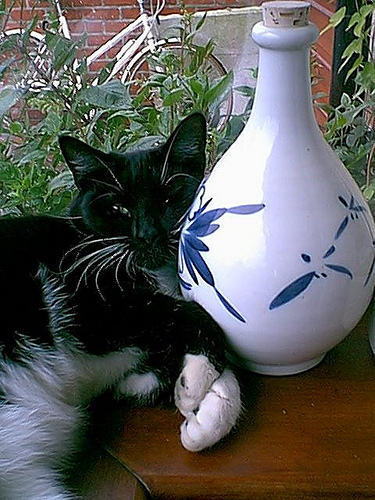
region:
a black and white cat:
[4, 117, 265, 498]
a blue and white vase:
[149, 33, 373, 388]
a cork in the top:
[261, 1, 322, 37]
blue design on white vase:
[164, 178, 371, 333]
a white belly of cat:
[12, 346, 116, 499]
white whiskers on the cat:
[54, 224, 170, 298]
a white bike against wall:
[18, 3, 244, 162]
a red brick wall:
[6, 3, 338, 161]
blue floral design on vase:
[176, 173, 373, 312]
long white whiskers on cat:
[49, 233, 145, 291]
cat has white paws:
[170, 354, 243, 453]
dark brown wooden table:
[258, 382, 355, 480]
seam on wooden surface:
[89, 435, 148, 497]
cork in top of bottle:
[259, 0, 314, 28]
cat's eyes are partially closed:
[103, 194, 186, 215]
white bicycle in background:
[1, 1, 235, 136]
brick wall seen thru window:
[83, 2, 115, 31]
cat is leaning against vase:
[169, 170, 208, 309]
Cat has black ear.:
[157, 140, 206, 160]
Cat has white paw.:
[192, 396, 231, 447]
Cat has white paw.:
[180, 369, 204, 408]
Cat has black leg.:
[124, 295, 198, 328]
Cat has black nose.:
[139, 227, 152, 245]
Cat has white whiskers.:
[85, 241, 118, 268]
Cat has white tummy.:
[20, 400, 68, 464]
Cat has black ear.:
[63, 143, 99, 173]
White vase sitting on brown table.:
[244, 346, 331, 414]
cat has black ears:
[56, 131, 177, 180]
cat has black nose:
[124, 219, 160, 249]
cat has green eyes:
[72, 195, 184, 221]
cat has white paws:
[119, 353, 258, 470]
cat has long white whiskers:
[63, 216, 138, 292]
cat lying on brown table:
[24, 202, 300, 477]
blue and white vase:
[221, 57, 360, 384]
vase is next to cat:
[60, 89, 349, 384]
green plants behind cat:
[13, 60, 210, 190]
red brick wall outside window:
[33, 1, 168, 117]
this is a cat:
[2, 110, 236, 491]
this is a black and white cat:
[7, 106, 234, 494]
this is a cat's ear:
[56, 124, 117, 186]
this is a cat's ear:
[154, 108, 210, 188]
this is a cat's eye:
[104, 202, 137, 235]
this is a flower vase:
[177, 4, 368, 380]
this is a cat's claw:
[170, 357, 203, 414]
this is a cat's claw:
[181, 403, 230, 450]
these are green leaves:
[27, 36, 121, 124]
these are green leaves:
[159, 55, 235, 106]